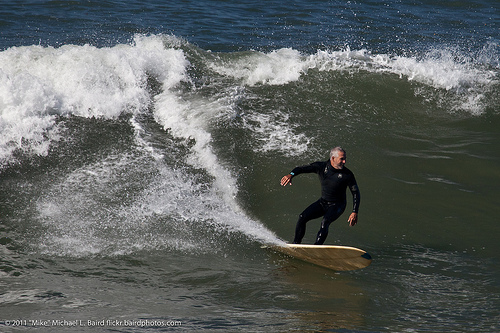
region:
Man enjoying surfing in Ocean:
[1, 6, 492, 326]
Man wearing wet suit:
[255, 130, 385, 275]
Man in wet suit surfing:
[262, 136, 374, 276]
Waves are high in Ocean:
[5, 10, 490, 135]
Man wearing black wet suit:
[270, 140, 375, 270]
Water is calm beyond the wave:
[0, 5, 485, 140]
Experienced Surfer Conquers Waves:
[17, 30, 488, 291]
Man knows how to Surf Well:
[197, 31, 387, 281]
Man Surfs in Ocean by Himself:
[5, 2, 495, 327]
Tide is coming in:
[7, 16, 494, 142]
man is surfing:
[259, 126, 386, 270]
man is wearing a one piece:
[274, 151, 386, 251]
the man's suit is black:
[276, 148, 371, 250]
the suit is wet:
[268, 137, 370, 245]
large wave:
[1, 37, 199, 194]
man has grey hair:
[325, 133, 350, 171]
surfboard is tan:
[236, 231, 383, 277]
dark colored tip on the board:
[356, 248, 379, 265]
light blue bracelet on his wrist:
[278, 164, 305, 177]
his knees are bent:
[285, 186, 357, 251]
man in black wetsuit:
[150, 120, 410, 285]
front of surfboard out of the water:
[240, 200, 380, 285]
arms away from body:
[267, 130, 392, 235]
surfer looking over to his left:
[280, 115, 380, 205]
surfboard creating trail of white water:
[145, 120, 361, 261]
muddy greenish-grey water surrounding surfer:
[151, 102, 441, 282]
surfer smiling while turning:
[296, 125, 366, 215]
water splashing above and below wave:
[406, 32, 492, 123]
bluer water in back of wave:
[100, 10, 475, 50]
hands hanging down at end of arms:
[275, 165, 361, 235]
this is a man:
[282, 138, 362, 244]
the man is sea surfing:
[272, 139, 363, 271]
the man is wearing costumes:
[303, 172, 348, 222]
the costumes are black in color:
[306, 169, 346, 220]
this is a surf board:
[297, 237, 373, 257]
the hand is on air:
[276, 158, 309, 188]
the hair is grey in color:
[330, 149, 336, 156]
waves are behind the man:
[0, 30, 254, 232]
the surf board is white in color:
[288, 240, 371, 258]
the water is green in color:
[325, 75, 390, 118]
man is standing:
[272, 145, 361, 244]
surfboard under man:
[263, 243, 372, 280]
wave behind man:
[0, 32, 499, 274]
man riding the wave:
[278, 141, 362, 243]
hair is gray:
[329, 145, 346, 159]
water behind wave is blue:
[1, 2, 498, 74]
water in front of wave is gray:
[1, 37, 499, 332]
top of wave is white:
[0, 32, 277, 157]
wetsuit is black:
[280, 146, 361, 250]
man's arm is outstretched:
[277, 161, 322, 200]